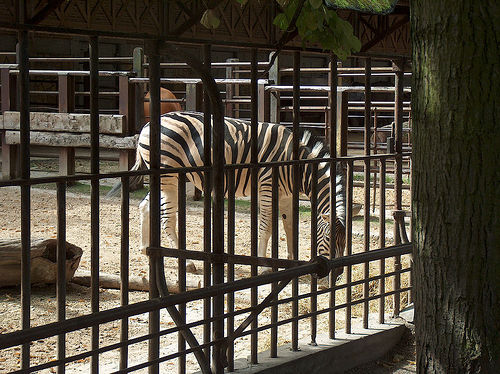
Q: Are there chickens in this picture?
A: No, there are no chickens.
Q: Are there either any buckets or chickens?
A: No, there are no chickens or buckets.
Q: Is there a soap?
A: No, there are no soaps.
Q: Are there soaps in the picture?
A: No, there are no soaps.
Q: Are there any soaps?
A: No, there are no soaps.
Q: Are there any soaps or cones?
A: No, there are no soaps or cones.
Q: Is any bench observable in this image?
A: No, there are no benches.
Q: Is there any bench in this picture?
A: No, there are no benches.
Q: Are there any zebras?
A: Yes, there is a zebra.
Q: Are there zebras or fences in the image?
A: Yes, there is a zebra.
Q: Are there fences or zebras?
A: Yes, there is a zebra.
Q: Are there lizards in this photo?
A: No, there are no lizards.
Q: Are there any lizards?
A: No, there are no lizards.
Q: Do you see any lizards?
A: No, there are no lizards.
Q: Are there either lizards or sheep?
A: No, there are no lizards or sheep.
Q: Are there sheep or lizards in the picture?
A: No, there are no lizards or sheep.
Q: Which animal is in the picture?
A: The animal is a zebra.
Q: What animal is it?
A: The animal is a zebra.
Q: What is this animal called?
A: This is a zebra.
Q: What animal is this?
A: This is a zebra.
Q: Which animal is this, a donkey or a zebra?
A: This is a zebra.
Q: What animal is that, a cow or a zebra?
A: That is a zebra.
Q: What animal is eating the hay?
A: The zebra is eating the hay.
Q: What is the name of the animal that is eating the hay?
A: The animal is a zebra.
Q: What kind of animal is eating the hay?
A: The animal is a zebra.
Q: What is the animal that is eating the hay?
A: The animal is a zebra.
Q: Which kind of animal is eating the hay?
A: The animal is a zebra.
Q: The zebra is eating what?
A: The zebra is eating hay.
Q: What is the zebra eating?
A: The zebra is eating hay.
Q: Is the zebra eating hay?
A: Yes, the zebra is eating hay.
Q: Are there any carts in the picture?
A: No, there are no carts.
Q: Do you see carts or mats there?
A: No, there are no carts or mats.